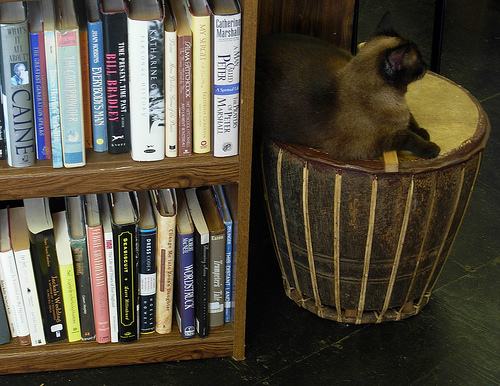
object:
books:
[213, 0, 240, 158]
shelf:
[0, 184, 251, 374]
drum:
[262, 70, 491, 325]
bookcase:
[0, 0, 260, 177]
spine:
[116, 218, 140, 344]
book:
[108, 190, 140, 342]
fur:
[279, 63, 311, 103]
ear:
[373, 11, 395, 36]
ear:
[381, 45, 401, 76]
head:
[360, 13, 429, 88]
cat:
[252, 32, 440, 161]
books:
[0, 1, 35, 170]